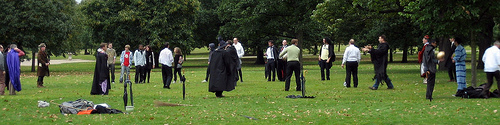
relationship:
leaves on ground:
[25, 100, 497, 125] [6, 53, 499, 124]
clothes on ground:
[37, 95, 119, 121] [6, 53, 499, 124]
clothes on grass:
[59, 99, 124, 116] [0, 51, 498, 124]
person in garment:
[6, 35, 500, 97] [86, 49, 114, 95]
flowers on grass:
[233, 100, 343, 118] [0, 51, 498, 124]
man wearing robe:
[6, 35, 500, 97] [204, 43, 243, 93]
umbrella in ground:
[115, 72, 307, 111] [3, 60, 484, 120]